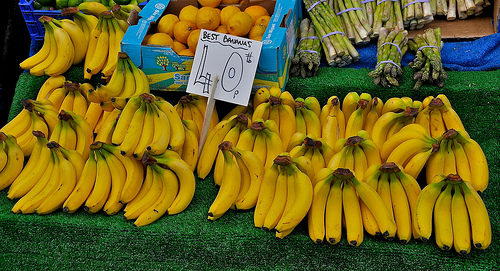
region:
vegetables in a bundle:
[410, 28, 446, 87]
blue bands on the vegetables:
[320, 31, 345, 39]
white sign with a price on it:
[183, 28, 261, 104]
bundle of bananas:
[206, 143, 266, 223]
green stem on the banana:
[115, 59, 135, 72]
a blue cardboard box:
[121, 0, 300, 86]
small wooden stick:
[199, 76, 217, 148]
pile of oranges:
[153, 2, 258, 49]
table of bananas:
[2, 5, 492, 250]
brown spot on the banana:
[152, 206, 157, 212]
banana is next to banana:
[207, 141, 241, 217]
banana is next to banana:
[155, 157, 195, 214]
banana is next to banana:
[133, 163, 179, 227]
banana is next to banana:
[123, 167, 161, 220]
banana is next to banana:
[232, 144, 264, 210]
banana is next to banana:
[253, 156, 277, 226]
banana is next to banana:
[262, 165, 286, 227]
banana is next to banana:
[277, 160, 299, 237]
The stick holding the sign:
[203, 75, 224, 166]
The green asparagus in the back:
[306, 6, 493, 120]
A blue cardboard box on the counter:
[140, 13, 292, 95]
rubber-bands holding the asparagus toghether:
[366, 32, 398, 83]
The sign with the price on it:
[202, 16, 267, 121]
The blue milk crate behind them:
[23, 9, 108, 61]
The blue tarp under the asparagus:
[349, 16, 497, 76]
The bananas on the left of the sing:
[27, 33, 191, 237]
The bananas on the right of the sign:
[206, 79, 491, 259]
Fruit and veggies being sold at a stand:
[29, 5, 479, 249]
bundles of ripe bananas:
[2, 93, 489, 224]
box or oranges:
[136, 0, 291, 96]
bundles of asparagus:
[299, 1, 438, 63]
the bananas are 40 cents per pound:
[188, 29, 261, 103]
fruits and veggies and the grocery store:
[16, 0, 482, 232]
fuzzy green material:
[9, 227, 111, 259]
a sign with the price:
[188, 30, 260, 160]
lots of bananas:
[5, 89, 489, 218]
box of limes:
[21, 0, 71, 38]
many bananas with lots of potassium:
[11, 95, 469, 220]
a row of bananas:
[2, 135, 483, 251]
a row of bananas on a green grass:
[12, 139, 499, 257]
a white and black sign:
[178, 23, 265, 108]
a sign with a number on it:
[186, 25, 269, 104]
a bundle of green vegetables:
[367, 26, 451, 93]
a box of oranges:
[121, 1, 299, 93]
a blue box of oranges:
[119, 1, 299, 92]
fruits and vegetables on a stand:
[2, 0, 495, 252]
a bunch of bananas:
[411, 171, 491, 252]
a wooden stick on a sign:
[191, 78, 221, 149]